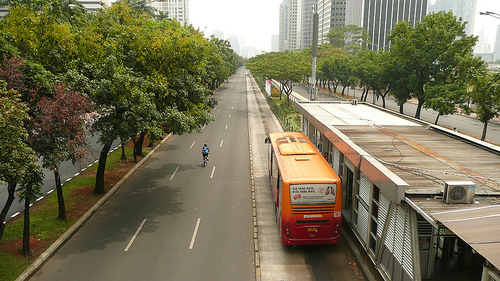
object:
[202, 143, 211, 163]
bicyclist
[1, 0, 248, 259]
tree row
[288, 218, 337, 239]
trunk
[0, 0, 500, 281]
picture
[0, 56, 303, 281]
outdoors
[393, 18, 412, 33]
leaves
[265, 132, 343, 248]
bus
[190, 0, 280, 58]
sky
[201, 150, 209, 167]
bicycle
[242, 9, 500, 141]
trees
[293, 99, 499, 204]
roof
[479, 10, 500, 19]
street lights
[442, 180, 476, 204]
unit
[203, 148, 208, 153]
blue riding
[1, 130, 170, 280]
median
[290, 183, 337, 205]
advertisement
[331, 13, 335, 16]
window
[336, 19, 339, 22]
window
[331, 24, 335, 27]
window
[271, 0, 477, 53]
buiding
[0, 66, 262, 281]
highway